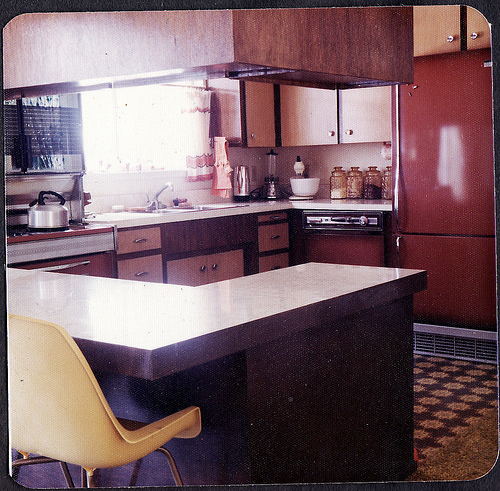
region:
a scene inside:
[13, 12, 495, 486]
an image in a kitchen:
[5, 3, 499, 478]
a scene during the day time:
[5, 0, 473, 490]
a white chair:
[0, 301, 224, 482]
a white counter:
[0, 243, 441, 363]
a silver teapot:
[12, 179, 86, 243]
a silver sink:
[103, 158, 258, 242]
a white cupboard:
[222, 61, 410, 182]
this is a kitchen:
[8, 16, 487, 451]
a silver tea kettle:
[15, 173, 92, 250]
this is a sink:
[126, 195, 241, 222]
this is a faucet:
[135, 165, 185, 205]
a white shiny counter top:
[25, 238, 438, 380]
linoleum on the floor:
[392, 320, 497, 483]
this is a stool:
[10, 288, 210, 485]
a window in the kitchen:
[62, 65, 233, 192]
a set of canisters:
[312, 146, 407, 208]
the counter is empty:
[68, 263, 342, 345]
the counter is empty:
[108, 260, 405, 387]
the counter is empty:
[85, 283, 449, 388]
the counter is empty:
[48, 248, 373, 358]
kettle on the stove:
[15, 185, 88, 253]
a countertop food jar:
[329, 163, 344, 199]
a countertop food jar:
[346, 165, 361, 199]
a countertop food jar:
[364, 163, 380, 201]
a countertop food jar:
[383, 163, 395, 198]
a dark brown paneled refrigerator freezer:
[389, 50, 499, 362]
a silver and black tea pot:
[26, 190, 71, 229]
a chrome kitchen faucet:
[145, 180, 174, 210]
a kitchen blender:
[260, 149, 282, 203]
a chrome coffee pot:
[231, 163, 251, 200]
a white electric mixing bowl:
[287, 154, 321, 203]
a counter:
[213, 277, 279, 313]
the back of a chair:
[23, 352, 80, 409]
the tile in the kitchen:
[423, 370, 470, 406]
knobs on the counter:
[196, 257, 224, 273]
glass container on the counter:
[346, 163, 365, 199]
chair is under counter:
[7, 303, 202, 489]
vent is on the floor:
[412, 322, 498, 364]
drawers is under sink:
[115, 227, 164, 253]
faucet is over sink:
[149, 180, 176, 205]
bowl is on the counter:
[289, 173, 319, 195]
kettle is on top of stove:
[30, 190, 67, 230]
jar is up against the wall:
[330, 165, 348, 198]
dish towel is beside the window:
[214, 137, 231, 197]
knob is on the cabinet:
[329, 130, 335, 136]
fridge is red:
[391, 47, 498, 324]